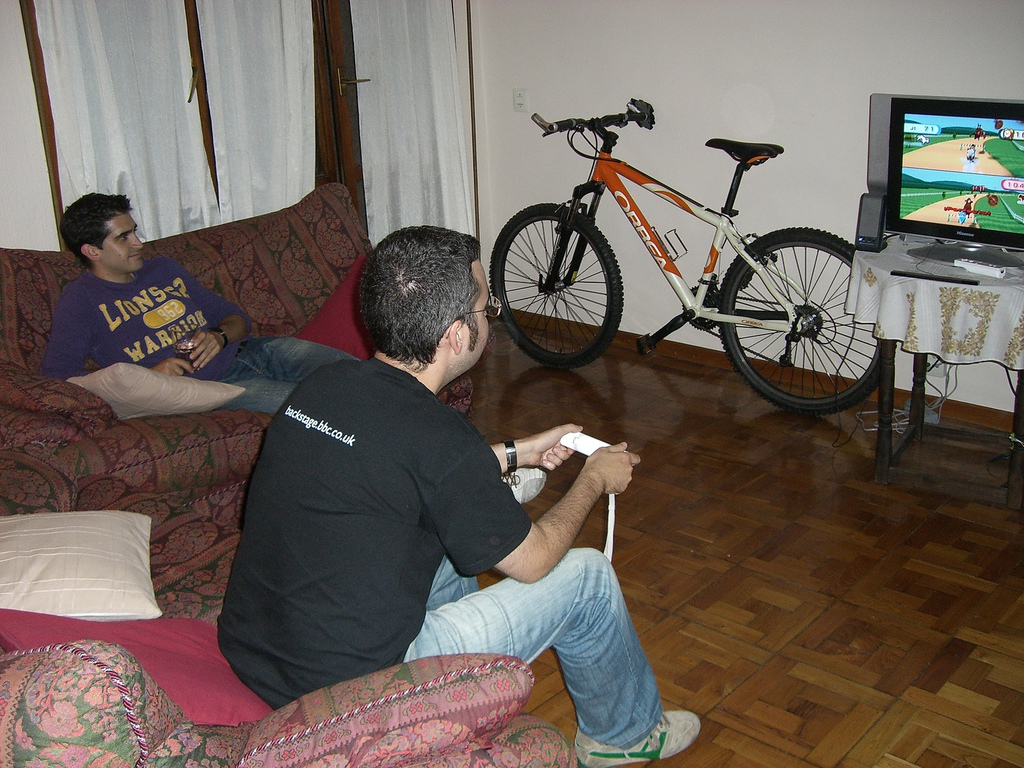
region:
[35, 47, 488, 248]
curtains hanging from the window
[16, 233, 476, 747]
a colorful couch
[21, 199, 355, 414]
a man laying on a couch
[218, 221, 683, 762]
a man in a black shirt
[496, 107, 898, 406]
an orange and white bicycle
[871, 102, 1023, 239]
a television on a desk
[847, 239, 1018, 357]
a white tablecloth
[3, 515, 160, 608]
a pillow on the sofa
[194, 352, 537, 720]
THE MAN IS WEARING A BLACK SHIRT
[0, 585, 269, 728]
THE PILLOW IS DARK PINK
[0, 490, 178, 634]
THE PILLOW IS LIGHT PINK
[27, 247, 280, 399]
THE MAN IS WEARING A BLUE SHIRT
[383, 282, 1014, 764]
THE FLOOR IS BROWN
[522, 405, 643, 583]
THE MAN IS HOLDING A CONTROLLER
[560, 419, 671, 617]
THE CONTROLLER IS WHITE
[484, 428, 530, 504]
THE MAN IS WEARING A WATCH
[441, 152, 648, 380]
front tire of bike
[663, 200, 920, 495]
back tire of bike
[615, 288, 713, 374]
pedal on the bike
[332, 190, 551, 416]
head of the man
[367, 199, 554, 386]
man with glasses on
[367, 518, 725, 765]
blue pants on the man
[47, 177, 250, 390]
man in a dark shirt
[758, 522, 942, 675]
brown ground in room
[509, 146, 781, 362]
orange and white object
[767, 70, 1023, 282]
screen in the room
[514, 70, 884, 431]
bike against the wall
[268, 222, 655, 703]
man playing a video game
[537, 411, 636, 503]
white controller in hand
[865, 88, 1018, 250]
tv sitting on a table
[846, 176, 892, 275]
speaker sitting beside the tv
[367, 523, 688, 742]
THE MAN IS WEARING JEANS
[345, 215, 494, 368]
THE MAN IS WEARING SHORT BLACK HAIR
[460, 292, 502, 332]
THE MAN IS WEARING GLASSES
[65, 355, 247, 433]
THE PILLOW IS BEIGE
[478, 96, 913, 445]
THE BIKE IS ORANGE AND WHITE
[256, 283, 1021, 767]
THE FLOOR IS SHINY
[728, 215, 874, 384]
a tire on the bike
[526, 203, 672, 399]
a tire on the bike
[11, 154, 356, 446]
a man sitting down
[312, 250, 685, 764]
a person sitting down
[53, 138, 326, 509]
a person sitting down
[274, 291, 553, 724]
a person wearing a shirt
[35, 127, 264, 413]
a person wearing a shirt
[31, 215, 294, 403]
a person wearing a purple shirt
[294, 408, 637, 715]
a person wearing jeans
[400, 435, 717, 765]
a person wearing blue jeans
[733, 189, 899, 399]
a tire on the bike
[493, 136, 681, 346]
a tire on the bike